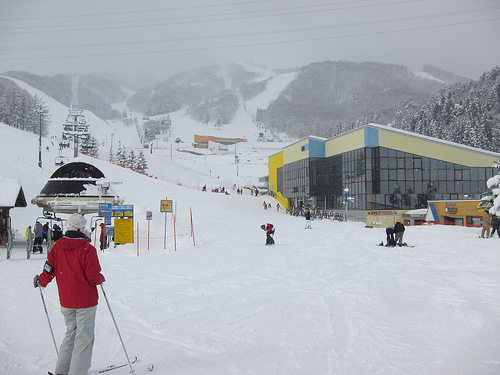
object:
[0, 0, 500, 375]
snow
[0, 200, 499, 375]
ground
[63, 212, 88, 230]
cap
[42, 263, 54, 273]
arm band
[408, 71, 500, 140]
tree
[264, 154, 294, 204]
yellow portion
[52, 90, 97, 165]
ski chair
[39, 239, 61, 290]
arm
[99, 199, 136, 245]
signs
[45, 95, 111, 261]
lift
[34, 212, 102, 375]
person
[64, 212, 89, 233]
head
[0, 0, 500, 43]
power line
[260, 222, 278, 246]
person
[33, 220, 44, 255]
person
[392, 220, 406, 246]
person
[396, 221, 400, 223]
head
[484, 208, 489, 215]
head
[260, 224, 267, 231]
head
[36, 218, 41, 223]
head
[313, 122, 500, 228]
lodge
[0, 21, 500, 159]
mountains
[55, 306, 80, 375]
leg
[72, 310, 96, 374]
leg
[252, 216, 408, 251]
people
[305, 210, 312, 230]
skier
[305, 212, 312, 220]
jacket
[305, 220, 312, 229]
pants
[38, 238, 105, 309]
jacket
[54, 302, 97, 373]
pants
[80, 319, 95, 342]
part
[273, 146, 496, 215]
window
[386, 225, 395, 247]
skier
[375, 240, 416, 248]
equipment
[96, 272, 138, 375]
ski pole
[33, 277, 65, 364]
ski pole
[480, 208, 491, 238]
person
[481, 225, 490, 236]
leg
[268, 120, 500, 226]
building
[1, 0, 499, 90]
sky